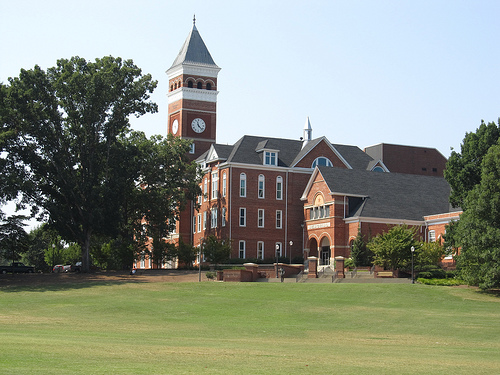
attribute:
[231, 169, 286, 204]
windows — arched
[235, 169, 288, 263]
windows — group, nine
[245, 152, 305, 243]
window — part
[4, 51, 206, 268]
tree — big, green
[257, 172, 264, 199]
window — part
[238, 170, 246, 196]
window — part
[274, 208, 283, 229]
window — part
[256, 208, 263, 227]
window — part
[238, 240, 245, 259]
window — part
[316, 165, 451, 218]
house — part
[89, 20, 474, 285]
building — very dignified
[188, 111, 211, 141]
clock — analog, steeple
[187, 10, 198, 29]
cross — at top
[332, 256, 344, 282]
column — brick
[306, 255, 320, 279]
column — brick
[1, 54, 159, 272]
tree — big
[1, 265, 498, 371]
lawn — huge, wide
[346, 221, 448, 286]
tree — small 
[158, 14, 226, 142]
steeple — brick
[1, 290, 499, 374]
lawn — big, green, yellow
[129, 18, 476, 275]
building — part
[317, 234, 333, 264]
doorway — arched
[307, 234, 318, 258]
doorway — arched